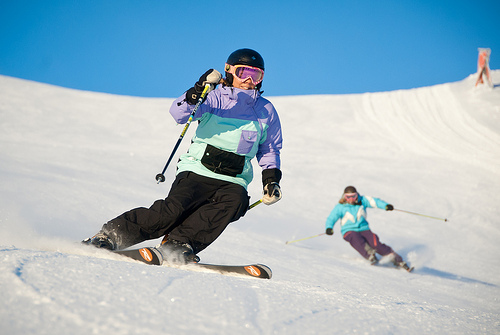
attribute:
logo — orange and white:
[241, 260, 261, 280]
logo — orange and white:
[136, 244, 154, 265]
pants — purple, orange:
[341, 230, 421, 277]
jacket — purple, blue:
[166, 83, 280, 191]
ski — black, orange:
[106, 247, 170, 265]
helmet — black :
[225, 48, 269, 89]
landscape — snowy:
[341, 110, 408, 145]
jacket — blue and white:
[321, 197, 389, 230]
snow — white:
[5, 82, 85, 322]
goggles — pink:
[223, 62, 266, 84]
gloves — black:
[259, 167, 285, 204]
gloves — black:
[185, 67, 222, 105]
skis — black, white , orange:
[112, 238, 271, 278]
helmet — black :
[215, 42, 276, 83]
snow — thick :
[5, 64, 491, 330]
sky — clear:
[5, 2, 497, 85]